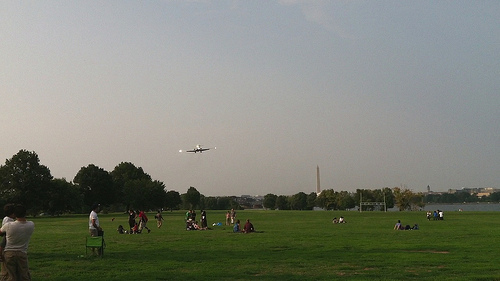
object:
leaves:
[12, 161, 29, 182]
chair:
[81, 235, 108, 260]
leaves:
[27, 168, 46, 182]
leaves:
[55, 194, 73, 213]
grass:
[2, 209, 499, 281]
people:
[242, 218, 256, 234]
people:
[393, 219, 405, 231]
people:
[231, 219, 241, 233]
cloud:
[0, 0, 499, 200]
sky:
[0, 0, 499, 197]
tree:
[0, 147, 245, 220]